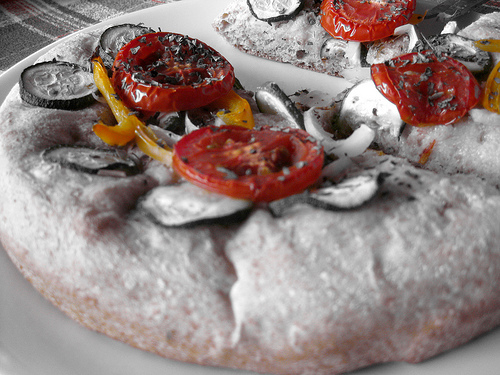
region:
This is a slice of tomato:
[169, 113, 338, 193]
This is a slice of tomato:
[98, 27, 205, 107]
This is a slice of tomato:
[361, 50, 473, 145]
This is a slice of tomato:
[326, 5, 406, 43]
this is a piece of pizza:
[57, 207, 395, 367]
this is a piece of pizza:
[346, 239, 461, 356]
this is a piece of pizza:
[1, 197, 111, 309]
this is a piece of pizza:
[83, 205, 240, 350]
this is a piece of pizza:
[241, 234, 371, 348]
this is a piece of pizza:
[126, 260, 283, 354]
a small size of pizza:
[51, 14, 493, 328]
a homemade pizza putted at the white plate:
[14, 13, 364, 370]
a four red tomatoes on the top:
[102, 0, 482, 205]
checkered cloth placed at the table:
[15, 6, 90, 51]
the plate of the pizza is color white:
[7, 32, 102, 363]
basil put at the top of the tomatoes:
[132, 31, 207, 91]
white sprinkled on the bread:
[222, 223, 479, 360]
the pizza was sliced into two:
[21, 3, 476, 234]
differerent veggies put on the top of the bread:
[28, 11, 496, 157]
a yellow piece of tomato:
[90, 49, 227, 178]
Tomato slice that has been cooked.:
[111, 29, 235, 114]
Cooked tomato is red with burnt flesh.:
[112, 31, 235, 116]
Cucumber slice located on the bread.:
[17, 58, 102, 109]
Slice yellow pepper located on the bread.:
[90, 54, 176, 179]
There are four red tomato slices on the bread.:
[110, 1, 483, 206]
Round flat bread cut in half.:
[1, 0, 498, 374]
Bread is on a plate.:
[2, 1, 499, 373]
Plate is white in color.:
[4, 0, 498, 374]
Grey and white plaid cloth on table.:
[2, 1, 184, 71]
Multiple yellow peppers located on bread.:
[89, 33, 499, 168]